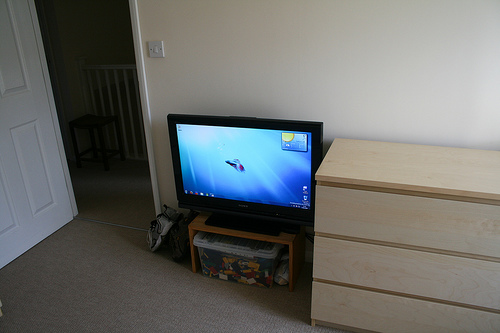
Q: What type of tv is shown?
A: Flat screen.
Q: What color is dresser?
A: Tan.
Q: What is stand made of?
A: Wood.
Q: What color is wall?
A: White.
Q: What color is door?
A: White.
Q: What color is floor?
A: Brown.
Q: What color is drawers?
A: Brown.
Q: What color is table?
A: Brown.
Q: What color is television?
A: Black.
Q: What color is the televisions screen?
A: Blue.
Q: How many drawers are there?
A: 3.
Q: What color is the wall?
A: White.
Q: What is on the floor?
A: Carpet.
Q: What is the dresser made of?
A: Wood.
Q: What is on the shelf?
A: A television.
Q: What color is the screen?
A: Blue.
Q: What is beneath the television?
A: A plastic tub.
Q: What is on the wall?
A: A light switch.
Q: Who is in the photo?
A: Nobody.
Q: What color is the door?
A: White.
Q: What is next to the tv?
A: A pair of shoes.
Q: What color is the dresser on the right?
A: Light brown.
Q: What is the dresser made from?
A: Wood.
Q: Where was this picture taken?
A: In a bedroom.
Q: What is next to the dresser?
A: A tv.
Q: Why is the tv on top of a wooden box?
A: To prop it up.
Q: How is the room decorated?
A: The room is bare.